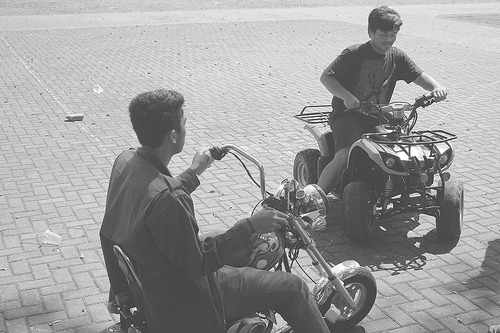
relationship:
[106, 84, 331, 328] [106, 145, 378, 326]
boy on bicycle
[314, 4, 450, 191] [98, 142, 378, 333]
boy on bicycle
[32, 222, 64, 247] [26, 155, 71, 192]
cup on ground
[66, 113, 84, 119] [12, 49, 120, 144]
rock on ground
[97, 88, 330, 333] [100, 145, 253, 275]
boy wearing collared shirt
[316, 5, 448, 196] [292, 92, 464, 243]
boy riding atv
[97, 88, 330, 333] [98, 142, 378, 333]
boy riding bicycle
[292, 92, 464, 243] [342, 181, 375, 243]
atv has rubber tire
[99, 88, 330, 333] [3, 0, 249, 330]
low rider on left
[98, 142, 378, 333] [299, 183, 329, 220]
bicycle has head lamp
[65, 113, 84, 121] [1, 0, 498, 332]
rock laying on ground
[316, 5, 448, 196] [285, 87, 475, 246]
boy riding atv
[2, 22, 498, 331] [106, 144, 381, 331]
surface under vehicles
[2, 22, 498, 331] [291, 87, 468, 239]
surface under vehicles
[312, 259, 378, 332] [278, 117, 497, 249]
rubber tire of vehicle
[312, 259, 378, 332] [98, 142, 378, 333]
rubber tire of bicycle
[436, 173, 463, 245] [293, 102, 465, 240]
rubber tire of vehicle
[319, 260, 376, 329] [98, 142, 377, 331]
tire of vehicle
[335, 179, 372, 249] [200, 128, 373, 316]
rubber tire of vehicles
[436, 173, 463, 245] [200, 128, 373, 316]
rubber tire of vehicles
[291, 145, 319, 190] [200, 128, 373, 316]
rubber tire of vehicles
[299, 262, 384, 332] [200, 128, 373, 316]
rubber tire of vehicles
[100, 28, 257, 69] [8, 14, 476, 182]
brick covering ground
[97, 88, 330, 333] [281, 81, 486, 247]
boy sitting on atv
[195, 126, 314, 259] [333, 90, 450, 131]
hand gripping handlebars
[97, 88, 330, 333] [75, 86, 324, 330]
boy wearing jacket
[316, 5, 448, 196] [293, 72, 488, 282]
boy smiling on atv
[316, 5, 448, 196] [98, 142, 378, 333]
boy on a bicycle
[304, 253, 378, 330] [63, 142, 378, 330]
front wheel of bike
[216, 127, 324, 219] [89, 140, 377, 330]
handles of low rider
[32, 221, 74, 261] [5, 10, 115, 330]
cup laying on ground